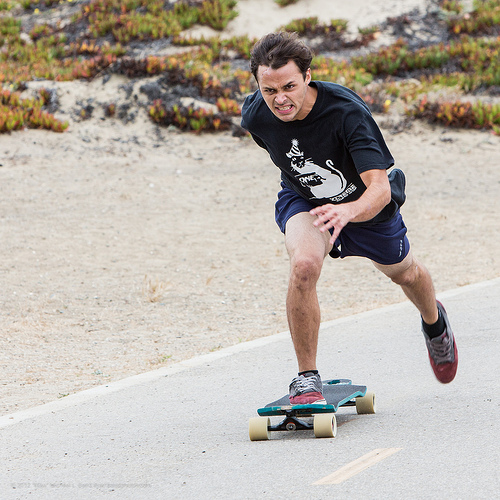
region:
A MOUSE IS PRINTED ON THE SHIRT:
[283, 145, 361, 195]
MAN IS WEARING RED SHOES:
[294, 308, 454, 408]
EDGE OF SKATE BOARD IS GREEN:
[256, 378, 373, 415]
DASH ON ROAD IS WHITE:
[311, 440, 403, 490]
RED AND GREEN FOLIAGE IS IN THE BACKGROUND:
[6, 0, 251, 118]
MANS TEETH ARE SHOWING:
[239, 43, 319, 120]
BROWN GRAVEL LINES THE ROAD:
[14, 140, 264, 402]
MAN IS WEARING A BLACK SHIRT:
[231, 93, 408, 200]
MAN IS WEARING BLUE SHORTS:
[270, 175, 421, 263]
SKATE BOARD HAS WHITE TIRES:
[242, 395, 392, 435]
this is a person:
[192, 36, 491, 433]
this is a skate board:
[249, 343, 382, 453]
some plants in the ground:
[120, 97, 225, 144]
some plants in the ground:
[422, 92, 499, 161]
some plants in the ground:
[367, 32, 457, 84]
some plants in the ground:
[170, 20, 219, 100]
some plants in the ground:
[22, 20, 105, 90]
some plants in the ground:
[105, 10, 189, 53]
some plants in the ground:
[279, 0, 353, 55]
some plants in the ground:
[112, 40, 239, 100]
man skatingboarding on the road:
[241, 33, 457, 441]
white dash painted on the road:
[309, 429, 391, 484]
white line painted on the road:
[2, 259, 497, 445]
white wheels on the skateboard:
[247, 384, 377, 439]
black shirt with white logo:
[228, 89, 386, 203]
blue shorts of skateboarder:
[273, 185, 412, 266]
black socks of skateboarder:
[293, 302, 445, 379]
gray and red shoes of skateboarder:
[286, 330, 460, 405]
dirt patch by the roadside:
[7, 129, 494, 396]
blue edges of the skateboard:
[269, 389, 367, 419]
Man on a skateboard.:
[242, 45, 450, 421]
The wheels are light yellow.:
[232, 418, 352, 446]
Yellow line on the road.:
[306, 434, 403, 493]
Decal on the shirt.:
[269, 130, 363, 203]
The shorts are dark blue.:
[279, 197, 403, 259]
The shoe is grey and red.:
[409, 320, 470, 391]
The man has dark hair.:
[239, 29, 317, 78]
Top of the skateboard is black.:
[292, 378, 356, 414]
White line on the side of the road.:
[0, 368, 188, 428]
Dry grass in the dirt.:
[135, 275, 176, 310]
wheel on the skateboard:
[302, 405, 339, 437]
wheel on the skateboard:
[360, 393, 376, 411]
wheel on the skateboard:
[248, 409, 278, 444]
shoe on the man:
[286, 375, 325, 412]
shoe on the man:
[418, 334, 464, 391]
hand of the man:
[306, 206, 354, 244]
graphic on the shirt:
[287, 141, 344, 199]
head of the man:
[251, 42, 312, 123]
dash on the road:
[333, 440, 410, 475]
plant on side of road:
[157, 103, 205, 138]